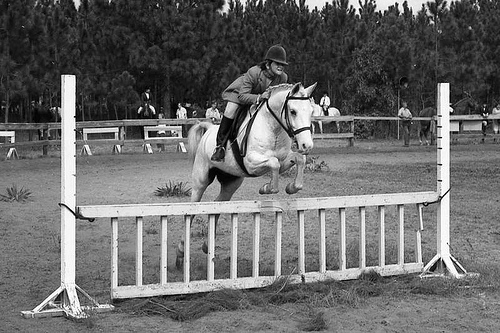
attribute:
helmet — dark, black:
[261, 44, 290, 67]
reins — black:
[237, 89, 312, 160]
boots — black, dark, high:
[208, 114, 235, 159]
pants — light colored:
[222, 100, 238, 120]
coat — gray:
[221, 65, 289, 106]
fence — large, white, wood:
[20, 72, 480, 326]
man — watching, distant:
[395, 98, 415, 148]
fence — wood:
[1, 113, 499, 162]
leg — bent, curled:
[243, 147, 282, 196]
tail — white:
[185, 119, 213, 165]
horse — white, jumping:
[171, 80, 317, 272]